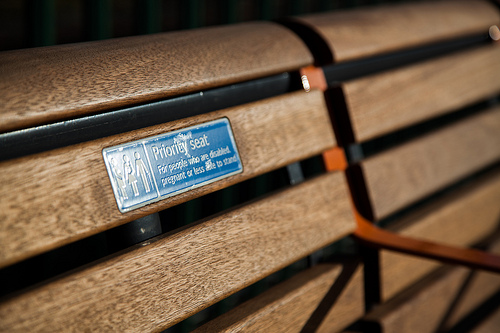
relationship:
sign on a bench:
[98, 113, 250, 215] [4, 1, 496, 328]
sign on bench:
[98, 113, 250, 215] [6, 24, 482, 331]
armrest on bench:
[351, 209, 483, 277] [6, 24, 482, 331]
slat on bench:
[1, 85, 335, 265] [6, 24, 482, 331]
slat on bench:
[6, 172, 354, 331] [6, 24, 482, 331]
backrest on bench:
[2, 21, 365, 329] [6, 24, 482, 331]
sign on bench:
[101, 117, 245, 215] [6, 24, 482, 331]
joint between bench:
[273, 19, 402, 331] [1, 19, 372, 330]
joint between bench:
[273, 19, 402, 331] [296, 5, 482, 330]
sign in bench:
[101, 117, 245, 215] [1, 19, 372, 330]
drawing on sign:
[108, 145, 156, 205] [101, 117, 245, 215]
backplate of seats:
[16, 19, 343, 325] [11, 4, 483, 324]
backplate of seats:
[0, 4, 498, 332] [11, 4, 483, 324]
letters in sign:
[149, 122, 235, 191] [98, 117, 242, 206]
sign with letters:
[101, 117, 245, 215] [150, 124, 238, 181]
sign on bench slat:
[98, 113, 250, 215] [7, 80, 356, 264]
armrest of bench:
[351, 210, 499, 276] [9, 21, 361, 314]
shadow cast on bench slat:
[305, 254, 374, 324] [195, 260, 375, 319]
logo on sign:
[110, 146, 162, 202] [89, 118, 247, 211]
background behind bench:
[6, 7, 297, 318] [10, 30, 421, 318]